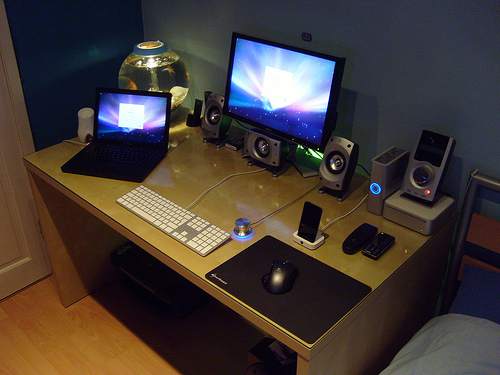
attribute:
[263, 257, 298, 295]
mouse — black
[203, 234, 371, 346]
mouse pad — black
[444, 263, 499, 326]
pillow — blue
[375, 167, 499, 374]
bed — wooden, brown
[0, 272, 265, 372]
floor — hardwood, light brown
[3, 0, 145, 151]
wall — dark blue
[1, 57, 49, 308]
door — white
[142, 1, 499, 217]
wall — light blue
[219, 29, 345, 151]
monitor — on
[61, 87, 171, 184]
laptop — on, black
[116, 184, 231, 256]
keyboard — white, gray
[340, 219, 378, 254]
remote control — black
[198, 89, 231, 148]
speaker — grey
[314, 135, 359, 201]
speaker — grey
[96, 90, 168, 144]
laptop screen — on